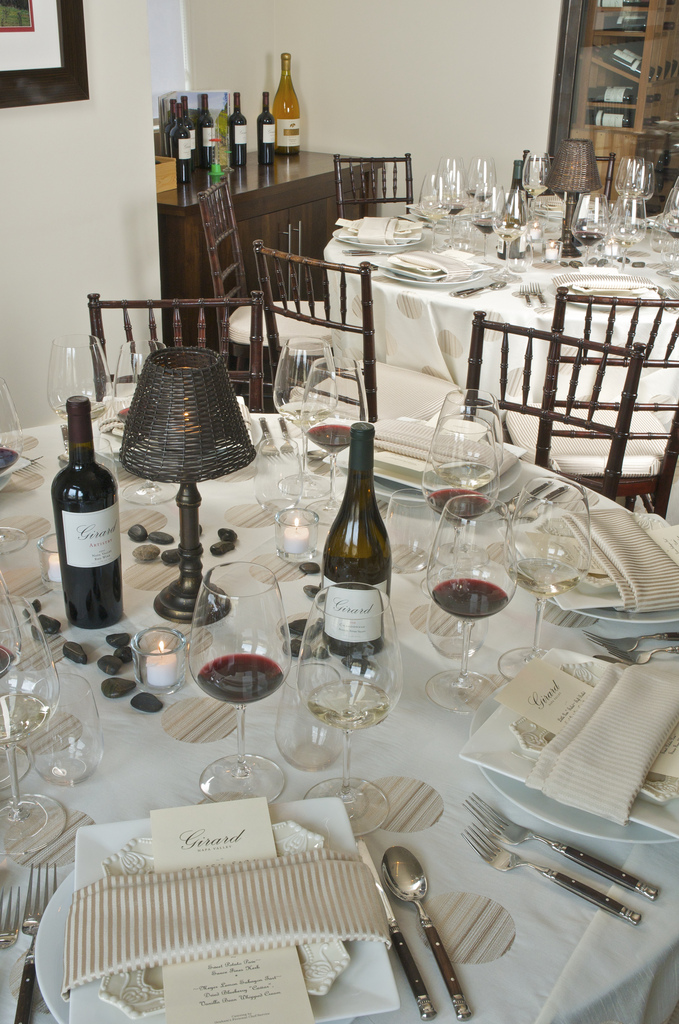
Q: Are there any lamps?
A: Yes, there is a lamp.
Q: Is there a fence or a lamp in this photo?
A: Yes, there is a lamp.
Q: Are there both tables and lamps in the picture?
A: Yes, there are both a lamp and a table.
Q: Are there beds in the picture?
A: No, there are no beds.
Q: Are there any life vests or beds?
A: No, there are no beds or life vests.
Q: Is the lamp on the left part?
A: Yes, the lamp is on the left of the image.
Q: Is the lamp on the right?
A: No, the lamp is on the left of the image.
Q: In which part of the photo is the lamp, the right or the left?
A: The lamp is on the left of the image.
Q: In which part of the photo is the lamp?
A: The lamp is on the left of the image.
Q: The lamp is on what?
A: The lamp is on the table.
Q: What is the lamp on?
A: The lamp is on the table.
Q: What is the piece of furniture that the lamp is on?
A: The piece of furniture is a table.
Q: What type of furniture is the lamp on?
A: The lamp is on the table.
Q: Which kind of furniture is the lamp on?
A: The lamp is on the table.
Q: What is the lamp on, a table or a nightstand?
A: The lamp is on a table.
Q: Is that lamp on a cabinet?
A: No, the lamp is on the table.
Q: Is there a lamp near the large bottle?
A: Yes, there is a lamp near the bottle.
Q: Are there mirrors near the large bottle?
A: No, there is a lamp near the bottle.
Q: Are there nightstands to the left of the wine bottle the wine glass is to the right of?
A: No, there is a lamp to the left of the wine bottle.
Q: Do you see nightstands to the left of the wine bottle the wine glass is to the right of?
A: No, there is a lamp to the left of the wine bottle.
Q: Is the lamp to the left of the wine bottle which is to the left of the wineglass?
A: Yes, the lamp is to the left of the wine bottle.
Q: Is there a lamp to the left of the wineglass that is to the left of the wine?
A: Yes, there is a lamp to the left of the wine glass.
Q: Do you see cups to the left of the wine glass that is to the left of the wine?
A: No, there is a lamp to the left of the wineglass.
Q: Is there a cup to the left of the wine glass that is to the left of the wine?
A: No, there is a lamp to the left of the wineglass.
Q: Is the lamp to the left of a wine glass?
A: Yes, the lamp is to the left of a wine glass.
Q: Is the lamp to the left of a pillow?
A: No, the lamp is to the left of a wine glass.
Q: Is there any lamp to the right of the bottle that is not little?
A: Yes, there is a lamp to the right of the bottle.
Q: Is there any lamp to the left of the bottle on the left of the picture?
A: No, the lamp is to the right of the bottle.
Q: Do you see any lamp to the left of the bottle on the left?
A: No, the lamp is to the right of the bottle.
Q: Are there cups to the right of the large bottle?
A: No, there is a lamp to the right of the bottle.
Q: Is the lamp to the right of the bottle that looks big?
A: Yes, the lamp is to the right of the bottle.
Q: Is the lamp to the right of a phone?
A: No, the lamp is to the right of the bottle.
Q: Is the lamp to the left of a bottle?
A: No, the lamp is to the right of a bottle.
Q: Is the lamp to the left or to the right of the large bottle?
A: The lamp is to the right of the bottle.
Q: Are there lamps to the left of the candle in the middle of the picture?
A: Yes, there is a lamp to the left of the candle.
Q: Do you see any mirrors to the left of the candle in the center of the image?
A: No, there is a lamp to the left of the candle.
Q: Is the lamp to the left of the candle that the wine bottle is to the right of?
A: Yes, the lamp is to the left of the candle.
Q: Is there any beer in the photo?
A: No, there is no beer.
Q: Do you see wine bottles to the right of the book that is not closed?
A: Yes, there are wine bottles to the right of the book.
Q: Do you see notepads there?
A: No, there are no notepads.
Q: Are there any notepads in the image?
A: No, there are no notepads.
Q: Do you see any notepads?
A: No, there are no notepads.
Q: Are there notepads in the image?
A: No, there are no notepads.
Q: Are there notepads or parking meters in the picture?
A: No, there are no notepads or parking meters.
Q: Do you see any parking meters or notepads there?
A: No, there are no notepads or parking meters.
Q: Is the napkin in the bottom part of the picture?
A: Yes, the napkin is in the bottom of the image.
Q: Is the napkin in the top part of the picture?
A: No, the napkin is in the bottom of the image.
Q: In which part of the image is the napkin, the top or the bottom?
A: The napkin is in the bottom of the image.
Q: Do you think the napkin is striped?
A: Yes, the napkin is striped.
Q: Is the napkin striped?
A: Yes, the napkin is striped.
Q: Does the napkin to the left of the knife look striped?
A: Yes, the napkin is striped.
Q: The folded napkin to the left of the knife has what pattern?
A: The napkin is striped.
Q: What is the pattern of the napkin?
A: The napkin is striped.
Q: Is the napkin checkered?
A: No, the napkin is striped.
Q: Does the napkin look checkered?
A: No, the napkin is striped.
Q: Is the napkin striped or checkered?
A: The napkin is striped.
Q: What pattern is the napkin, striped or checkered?
A: The napkin is striped.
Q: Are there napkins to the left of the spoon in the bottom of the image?
A: Yes, there is a napkin to the left of the spoon.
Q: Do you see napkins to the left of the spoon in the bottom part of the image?
A: Yes, there is a napkin to the left of the spoon.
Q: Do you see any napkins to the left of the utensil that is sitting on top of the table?
A: Yes, there is a napkin to the left of the spoon.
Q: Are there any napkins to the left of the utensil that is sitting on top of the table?
A: Yes, there is a napkin to the left of the spoon.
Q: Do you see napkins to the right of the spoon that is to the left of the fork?
A: No, the napkin is to the left of the spoon.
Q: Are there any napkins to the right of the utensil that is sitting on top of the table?
A: No, the napkin is to the left of the spoon.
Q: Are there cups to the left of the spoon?
A: No, there is a napkin to the left of the spoon.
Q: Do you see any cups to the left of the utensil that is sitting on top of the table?
A: No, there is a napkin to the left of the spoon.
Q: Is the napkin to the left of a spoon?
A: Yes, the napkin is to the left of a spoon.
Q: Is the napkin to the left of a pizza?
A: No, the napkin is to the left of a spoon.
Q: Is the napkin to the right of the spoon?
A: No, the napkin is to the left of the spoon.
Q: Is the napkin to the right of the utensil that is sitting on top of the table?
A: No, the napkin is to the left of the spoon.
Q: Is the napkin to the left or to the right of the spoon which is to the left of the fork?
A: The napkin is to the left of the spoon.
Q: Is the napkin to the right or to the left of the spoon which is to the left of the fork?
A: The napkin is to the left of the spoon.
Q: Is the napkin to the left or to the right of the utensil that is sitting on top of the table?
A: The napkin is to the left of the spoon.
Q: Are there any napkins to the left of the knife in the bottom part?
A: Yes, there is a napkin to the left of the knife.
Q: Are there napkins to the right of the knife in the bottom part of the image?
A: No, the napkin is to the left of the knife.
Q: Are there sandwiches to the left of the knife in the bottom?
A: No, there is a napkin to the left of the knife.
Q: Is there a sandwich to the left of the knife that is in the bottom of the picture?
A: No, there is a napkin to the left of the knife.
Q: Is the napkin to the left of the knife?
A: Yes, the napkin is to the left of the knife.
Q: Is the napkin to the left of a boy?
A: No, the napkin is to the left of the knife.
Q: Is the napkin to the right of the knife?
A: No, the napkin is to the left of the knife.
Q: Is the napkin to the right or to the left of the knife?
A: The napkin is to the left of the knife.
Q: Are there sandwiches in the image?
A: No, there are no sandwiches.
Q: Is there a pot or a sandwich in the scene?
A: No, there are no sandwiches or pots.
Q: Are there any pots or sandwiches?
A: No, there are no sandwiches or pots.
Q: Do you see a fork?
A: Yes, there is a fork.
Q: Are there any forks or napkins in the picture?
A: Yes, there is a fork.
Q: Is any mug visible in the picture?
A: No, there are no mugs.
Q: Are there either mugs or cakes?
A: No, there are no mugs or cakes.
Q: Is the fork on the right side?
A: Yes, the fork is on the right of the image.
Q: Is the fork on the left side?
A: No, the fork is on the right of the image.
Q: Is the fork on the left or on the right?
A: The fork is on the right of the image.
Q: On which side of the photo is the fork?
A: The fork is on the right of the image.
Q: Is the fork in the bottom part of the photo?
A: Yes, the fork is in the bottom of the image.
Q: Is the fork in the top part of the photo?
A: No, the fork is in the bottom of the image.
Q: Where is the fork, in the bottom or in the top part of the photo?
A: The fork is in the bottom of the image.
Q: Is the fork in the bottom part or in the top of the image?
A: The fork is in the bottom of the image.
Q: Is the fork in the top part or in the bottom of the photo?
A: The fork is in the bottom of the image.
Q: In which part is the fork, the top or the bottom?
A: The fork is in the bottom of the image.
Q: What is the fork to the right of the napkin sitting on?
A: The fork is sitting on the table.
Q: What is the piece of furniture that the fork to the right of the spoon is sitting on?
A: The piece of furniture is a table.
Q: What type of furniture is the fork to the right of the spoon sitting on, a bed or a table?
A: The fork is sitting on a table.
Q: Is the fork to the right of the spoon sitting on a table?
A: Yes, the fork is sitting on a table.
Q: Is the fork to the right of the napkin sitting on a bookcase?
A: No, the fork is sitting on a table.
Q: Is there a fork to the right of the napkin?
A: Yes, there is a fork to the right of the napkin.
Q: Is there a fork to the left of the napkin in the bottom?
A: No, the fork is to the right of the napkin.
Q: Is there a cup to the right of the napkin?
A: No, there is a fork to the right of the napkin.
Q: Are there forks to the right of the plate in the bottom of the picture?
A: Yes, there is a fork to the right of the plate.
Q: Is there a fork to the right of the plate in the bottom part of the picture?
A: Yes, there is a fork to the right of the plate.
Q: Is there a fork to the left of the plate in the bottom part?
A: No, the fork is to the right of the plate.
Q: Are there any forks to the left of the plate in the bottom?
A: No, the fork is to the right of the plate.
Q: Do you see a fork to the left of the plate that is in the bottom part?
A: No, the fork is to the right of the plate.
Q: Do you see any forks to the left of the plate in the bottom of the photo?
A: No, the fork is to the right of the plate.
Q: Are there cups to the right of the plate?
A: No, there is a fork to the right of the plate.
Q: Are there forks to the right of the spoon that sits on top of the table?
A: Yes, there is a fork to the right of the spoon.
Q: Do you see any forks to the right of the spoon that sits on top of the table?
A: Yes, there is a fork to the right of the spoon.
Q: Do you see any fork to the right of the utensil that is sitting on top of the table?
A: Yes, there is a fork to the right of the spoon.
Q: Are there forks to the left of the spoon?
A: No, the fork is to the right of the spoon.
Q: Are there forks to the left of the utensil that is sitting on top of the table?
A: No, the fork is to the right of the spoon.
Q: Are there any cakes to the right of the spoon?
A: No, there is a fork to the right of the spoon.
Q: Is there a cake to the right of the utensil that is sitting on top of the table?
A: No, there is a fork to the right of the spoon.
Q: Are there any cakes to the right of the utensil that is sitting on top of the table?
A: No, there is a fork to the right of the spoon.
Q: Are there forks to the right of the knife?
A: Yes, there is a fork to the right of the knife.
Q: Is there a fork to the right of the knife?
A: Yes, there is a fork to the right of the knife.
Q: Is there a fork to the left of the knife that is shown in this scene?
A: No, the fork is to the right of the knife.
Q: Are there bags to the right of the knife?
A: No, there is a fork to the right of the knife.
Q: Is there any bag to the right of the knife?
A: No, there is a fork to the right of the knife.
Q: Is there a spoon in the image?
A: Yes, there is a spoon.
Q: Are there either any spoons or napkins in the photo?
A: Yes, there is a spoon.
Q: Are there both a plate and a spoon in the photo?
A: Yes, there are both a spoon and a plate.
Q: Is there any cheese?
A: No, there is no cheese.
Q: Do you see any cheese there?
A: No, there is no cheese.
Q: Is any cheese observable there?
A: No, there is no cheese.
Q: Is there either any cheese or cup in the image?
A: No, there are no cheese or cups.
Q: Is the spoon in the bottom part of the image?
A: Yes, the spoon is in the bottom of the image.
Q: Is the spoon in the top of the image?
A: No, the spoon is in the bottom of the image.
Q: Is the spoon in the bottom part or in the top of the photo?
A: The spoon is in the bottom of the image.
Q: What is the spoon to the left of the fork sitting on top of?
A: The spoon is sitting on top of the table.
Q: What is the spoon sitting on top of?
A: The spoon is sitting on top of the table.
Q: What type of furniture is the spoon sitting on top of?
A: The spoon is sitting on top of the table.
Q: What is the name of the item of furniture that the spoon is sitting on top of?
A: The piece of furniture is a table.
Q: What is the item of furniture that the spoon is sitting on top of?
A: The piece of furniture is a table.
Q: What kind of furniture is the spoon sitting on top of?
A: The spoon is sitting on top of the table.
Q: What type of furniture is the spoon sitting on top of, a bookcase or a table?
A: The spoon is sitting on top of a table.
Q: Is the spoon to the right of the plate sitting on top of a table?
A: Yes, the spoon is sitting on top of a table.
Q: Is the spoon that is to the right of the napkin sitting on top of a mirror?
A: No, the spoon is sitting on top of a table.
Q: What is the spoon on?
A: The spoon is on the table.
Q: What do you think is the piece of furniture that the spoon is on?
A: The piece of furniture is a table.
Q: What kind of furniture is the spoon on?
A: The spoon is on the table.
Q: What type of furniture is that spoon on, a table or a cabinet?
A: The spoon is on a table.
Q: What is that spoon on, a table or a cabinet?
A: The spoon is on a table.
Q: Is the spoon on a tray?
A: No, the spoon is on the table.